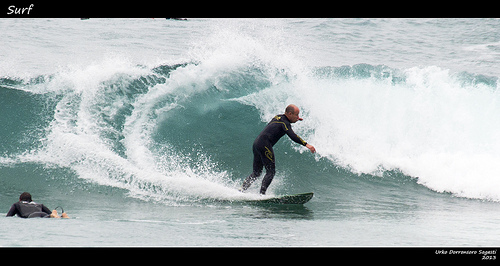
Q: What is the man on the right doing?
A: Surfing.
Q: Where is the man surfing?
A: In the ocean.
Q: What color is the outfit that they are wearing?
A: Black.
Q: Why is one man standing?
A: He is balancing.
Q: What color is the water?
A: White and green.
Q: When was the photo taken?
A: Day time.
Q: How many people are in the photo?
A: 2.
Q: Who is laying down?
A: The man on the left.